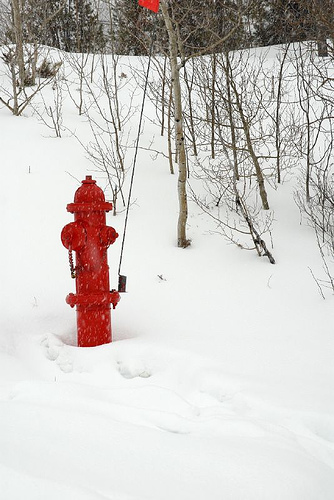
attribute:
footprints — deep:
[114, 357, 153, 380]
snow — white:
[0, 36, 333, 496]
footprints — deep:
[40, 338, 76, 374]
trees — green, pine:
[0, 0, 334, 299]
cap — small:
[105, 228, 119, 242]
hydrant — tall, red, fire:
[50, 174, 137, 349]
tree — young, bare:
[150, 0, 233, 248]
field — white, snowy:
[6, 49, 324, 493]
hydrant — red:
[61, 175, 120, 346]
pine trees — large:
[2, 0, 332, 59]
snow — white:
[76, 124, 164, 199]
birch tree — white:
[136, 3, 221, 246]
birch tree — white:
[1, 56, 34, 117]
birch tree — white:
[7, 0, 39, 85]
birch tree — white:
[65, 44, 90, 112]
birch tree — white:
[206, 50, 277, 204]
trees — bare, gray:
[2, 0, 329, 273]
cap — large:
[62, 169, 120, 215]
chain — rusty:
[66, 244, 79, 281]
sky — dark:
[229, 7, 303, 42]